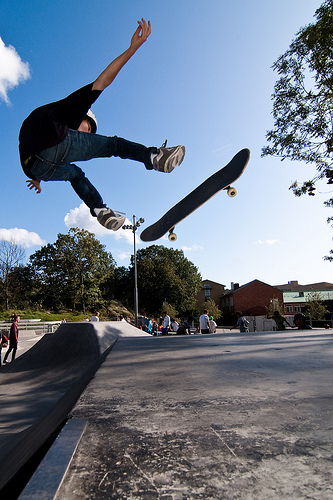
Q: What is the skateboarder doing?
A: Jumping.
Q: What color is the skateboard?
A: Black.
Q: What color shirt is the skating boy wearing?
A: Black.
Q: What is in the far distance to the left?
A: Trees.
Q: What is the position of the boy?
A: Mid-air.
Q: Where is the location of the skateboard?
A: Mid air.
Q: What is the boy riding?
A: A skateboard.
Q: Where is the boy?
A: At a skatepark.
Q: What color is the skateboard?
A: Black.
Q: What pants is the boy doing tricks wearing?
A: Bluejeans.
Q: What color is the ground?
A: Grey.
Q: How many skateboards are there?
A: One.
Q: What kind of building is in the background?
A: Brick.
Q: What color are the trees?
A: Green.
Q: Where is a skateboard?
A: In the air.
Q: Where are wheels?
A: On skateboard.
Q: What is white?
A: Clouds.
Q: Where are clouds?
A: In the sky.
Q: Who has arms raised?
A: Skateboarder.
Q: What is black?
A: Skateboard.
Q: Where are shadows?
A: On the ground.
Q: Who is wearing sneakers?
A: The skateboarder.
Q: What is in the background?
A: Buildings.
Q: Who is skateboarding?
A: The boy.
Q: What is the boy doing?
A: Skateboarding.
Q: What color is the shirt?
A: Black.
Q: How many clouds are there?
A: Three.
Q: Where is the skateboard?
A: In the air.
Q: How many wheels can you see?
A: Two.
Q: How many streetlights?
A: One.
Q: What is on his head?
A: A helmet.